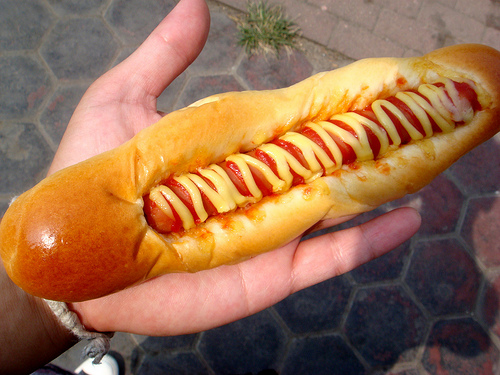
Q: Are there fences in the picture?
A: No, there are no fences.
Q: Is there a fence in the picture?
A: No, there are no fences.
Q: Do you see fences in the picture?
A: No, there are no fences.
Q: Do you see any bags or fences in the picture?
A: No, there are no fences or bags.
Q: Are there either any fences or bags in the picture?
A: No, there are no fences or bags.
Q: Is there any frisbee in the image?
A: No, there are no frisbees.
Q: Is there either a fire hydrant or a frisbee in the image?
A: No, there are no frisbees or fire hydrants.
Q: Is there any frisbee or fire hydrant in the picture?
A: No, there are no frisbees or fire hydrants.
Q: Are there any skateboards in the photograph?
A: No, there are no skateboards.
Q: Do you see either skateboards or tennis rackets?
A: No, there are no skateboards or tennis rackets.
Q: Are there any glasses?
A: No, there are no glasses.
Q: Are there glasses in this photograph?
A: No, there are no glasses.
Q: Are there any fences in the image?
A: No, there are no fences.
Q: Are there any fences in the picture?
A: No, there are no fences.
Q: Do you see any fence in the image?
A: No, there are no fences.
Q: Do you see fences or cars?
A: No, there are no fences or cars.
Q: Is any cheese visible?
A: Yes, there is cheese.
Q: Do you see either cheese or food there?
A: Yes, there is cheese.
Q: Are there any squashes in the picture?
A: No, there are no squashes.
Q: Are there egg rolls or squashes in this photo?
A: No, there are no squashes or egg rolls.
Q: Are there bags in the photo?
A: No, there are no bags.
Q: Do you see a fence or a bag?
A: No, there are no bags or fences.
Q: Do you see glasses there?
A: No, there are no glasses.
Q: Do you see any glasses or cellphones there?
A: No, there are no glasses or cellphones.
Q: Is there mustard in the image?
A: Yes, there is mustard.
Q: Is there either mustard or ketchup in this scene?
A: Yes, there is mustard.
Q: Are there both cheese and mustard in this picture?
A: Yes, there are both mustard and cheese.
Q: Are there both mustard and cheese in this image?
A: Yes, there are both mustard and cheese.